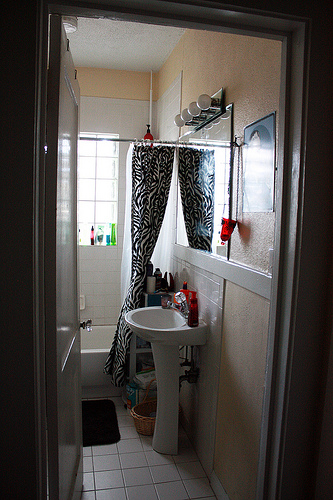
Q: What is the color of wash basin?
A: White.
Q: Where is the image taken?
A: In bathroom.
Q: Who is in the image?
A: No one.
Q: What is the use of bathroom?
A: To take bath.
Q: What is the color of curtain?
A: Black and white.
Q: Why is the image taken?
A: Remembrance.